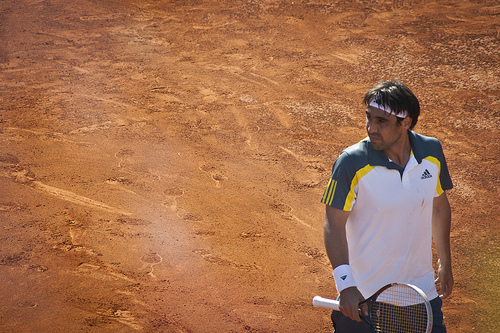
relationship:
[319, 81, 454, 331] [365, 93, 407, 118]
man wearing a headband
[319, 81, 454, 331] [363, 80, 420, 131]
man has hair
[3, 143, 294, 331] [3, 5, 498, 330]
foot prints in dirt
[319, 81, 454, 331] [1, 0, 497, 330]
man on court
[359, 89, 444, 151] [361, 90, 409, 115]
hair hanging over head band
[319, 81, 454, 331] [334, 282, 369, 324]
man has hand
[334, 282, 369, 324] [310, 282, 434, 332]
hand has racket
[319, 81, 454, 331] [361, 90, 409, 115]
man has head band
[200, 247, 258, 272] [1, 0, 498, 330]
foot prints on ground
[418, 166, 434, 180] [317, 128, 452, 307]
insignia on shirt